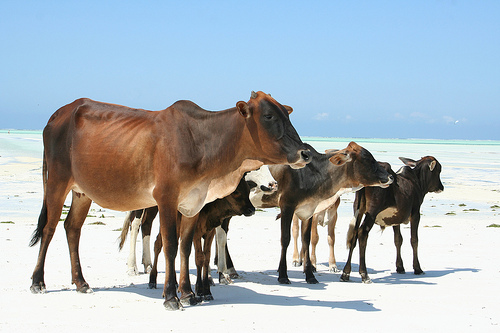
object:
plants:
[482, 221, 498, 228]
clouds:
[406, 111, 425, 122]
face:
[246, 163, 279, 184]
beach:
[0, 135, 498, 331]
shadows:
[45, 274, 387, 317]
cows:
[338, 155, 444, 283]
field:
[0, 143, 500, 333]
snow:
[0, 134, 496, 333]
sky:
[0, 0, 500, 138]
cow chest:
[172, 169, 238, 217]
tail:
[29, 148, 51, 258]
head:
[244, 163, 280, 195]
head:
[236, 88, 313, 170]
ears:
[235, 100, 252, 118]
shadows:
[215, 258, 332, 287]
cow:
[27, 90, 313, 311]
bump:
[161, 98, 206, 113]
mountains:
[385, 110, 464, 142]